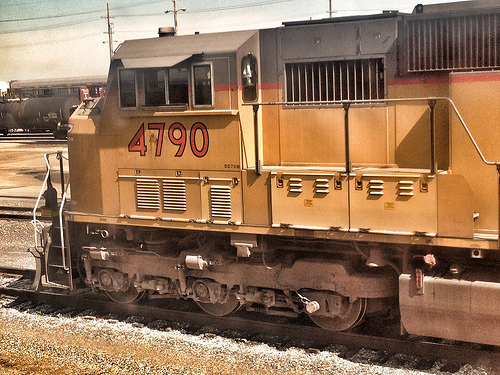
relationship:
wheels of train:
[83, 251, 387, 338] [21, 1, 500, 357]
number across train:
[123, 121, 213, 165] [21, 1, 500, 357]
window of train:
[193, 64, 215, 106] [21, 1, 500, 357]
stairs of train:
[25, 160, 70, 287] [21, 1, 500, 357]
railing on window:
[285, 61, 381, 98] [280, 45, 387, 112]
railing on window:
[412, 15, 483, 63] [401, 15, 479, 75]